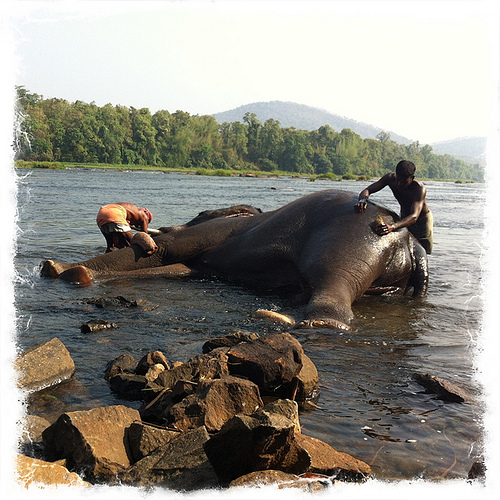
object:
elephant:
[39, 189, 429, 333]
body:
[38, 189, 429, 334]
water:
[24, 177, 95, 216]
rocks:
[14, 337, 76, 394]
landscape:
[14, 86, 489, 170]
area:
[24, 82, 495, 173]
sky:
[15, 0, 492, 139]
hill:
[209, 100, 421, 148]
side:
[144, 189, 428, 300]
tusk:
[131, 225, 165, 236]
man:
[96, 202, 153, 254]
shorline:
[18, 135, 495, 168]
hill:
[430, 136, 488, 160]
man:
[353, 160, 433, 255]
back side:
[362, 230, 425, 308]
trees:
[16, 84, 485, 182]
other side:
[21, 0, 486, 178]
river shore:
[22, 444, 374, 491]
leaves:
[31, 117, 45, 135]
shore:
[19, 160, 485, 183]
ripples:
[19, 286, 235, 333]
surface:
[448, 191, 479, 295]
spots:
[225, 348, 260, 364]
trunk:
[131, 224, 187, 255]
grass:
[124, 165, 156, 169]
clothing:
[96, 204, 132, 235]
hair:
[396, 160, 417, 178]